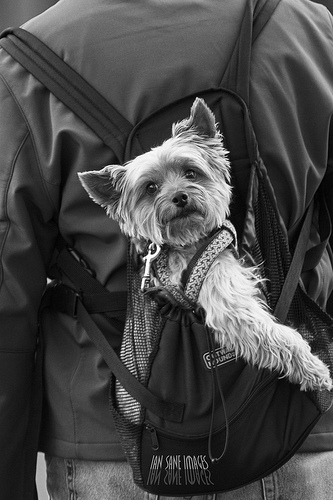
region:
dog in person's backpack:
[69, 130, 284, 393]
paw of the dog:
[264, 330, 325, 394]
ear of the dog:
[184, 98, 221, 142]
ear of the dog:
[75, 162, 124, 210]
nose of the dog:
[173, 191, 188, 209]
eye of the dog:
[146, 184, 157, 199]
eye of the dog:
[181, 167, 196, 188]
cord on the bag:
[200, 442, 225, 473]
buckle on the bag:
[59, 288, 88, 331]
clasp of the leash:
[141, 238, 160, 282]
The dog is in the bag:
[71, 116, 285, 382]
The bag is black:
[134, 347, 255, 483]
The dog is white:
[86, 131, 253, 304]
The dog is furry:
[216, 278, 322, 364]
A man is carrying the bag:
[52, 62, 307, 367]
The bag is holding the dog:
[94, 26, 306, 406]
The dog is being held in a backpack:
[68, 124, 283, 380]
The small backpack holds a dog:
[103, 135, 295, 476]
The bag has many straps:
[39, 92, 323, 445]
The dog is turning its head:
[82, 125, 226, 286]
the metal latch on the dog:
[140, 242, 160, 290]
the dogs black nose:
[172, 191, 188, 207]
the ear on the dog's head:
[76, 167, 125, 210]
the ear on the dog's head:
[171, 97, 215, 141]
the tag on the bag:
[203, 347, 238, 368]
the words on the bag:
[146, 454, 212, 488]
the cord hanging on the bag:
[192, 302, 228, 464]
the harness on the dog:
[141, 218, 237, 314]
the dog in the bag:
[78, 97, 332, 496]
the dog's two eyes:
[145, 167, 198, 195]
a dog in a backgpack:
[33, 71, 284, 286]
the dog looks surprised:
[89, 157, 313, 376]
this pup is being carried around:
[70, 114, 249, 251]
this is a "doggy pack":
[52, 92, 312, 338]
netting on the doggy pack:
[91, 275, 176, 413]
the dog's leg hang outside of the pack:
[202, 243, 332, 408]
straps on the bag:
[40, 262, 202, 416]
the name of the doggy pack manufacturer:
[120, 446, 238, 498]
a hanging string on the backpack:
[193, 331, 241, 473]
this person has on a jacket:
[2, 11, 329, 231]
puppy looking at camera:
[74, 102, 310, 390]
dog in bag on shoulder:
[72, 95, 319, 493]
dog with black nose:
[165, 189, 192, 210]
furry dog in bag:
[78, 97, 331, 391]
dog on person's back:
[5, 4, 329, 497]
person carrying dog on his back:
[6, 6, 328, 499]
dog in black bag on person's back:
[80, 92, 330, 493]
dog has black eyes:
[141, 166, 208, 196]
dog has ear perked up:
[163, 93, 231, 161]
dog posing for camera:
[78, 94, 330, 459]